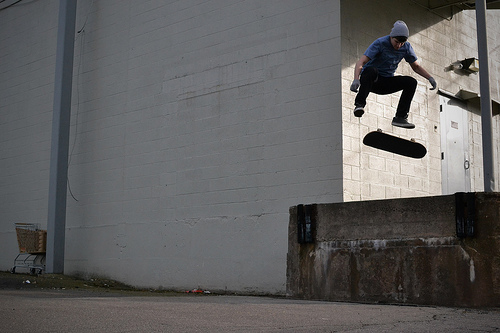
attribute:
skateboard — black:
[360, 125, 429, 162]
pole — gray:
[39, 0, 81, 276]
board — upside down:
[361, 125, 427, 160]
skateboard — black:
[354, 127, 436, 163]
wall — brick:
[77, 1, 287, 266]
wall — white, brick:
[3, 0, 498, 305]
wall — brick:
[0, 0, 345, 297]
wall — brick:
[84, 6, 309, 241]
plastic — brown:
[29, 238, 35, 250]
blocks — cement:
[188, 82, 347, 192]